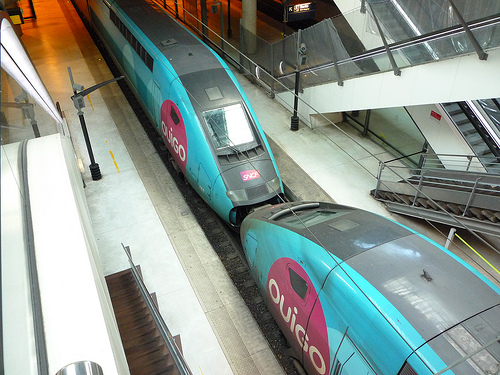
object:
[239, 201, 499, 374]
train engine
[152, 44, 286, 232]
train engine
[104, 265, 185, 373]
staircase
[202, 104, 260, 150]
windshield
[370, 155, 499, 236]
staircase